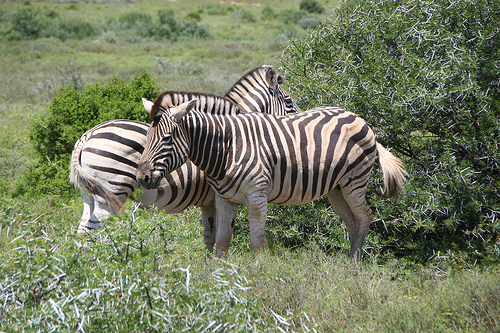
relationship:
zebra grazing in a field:
[134, 90, 412, 260] [1, 1, 483, 331]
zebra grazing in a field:
[66, 67, 303, 253] [1, 1, 483, 331]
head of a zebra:
[132, 91, 201, 191] [134, 90, 412, 260]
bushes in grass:
[6, 1, 212, 48] [1, 1, 241, 98]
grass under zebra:
[1, 196, 500, 333] [134, 98, 411, 261]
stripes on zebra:
[244, 113, 342, 201] [134, 90, 412, 260]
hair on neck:
[148, 90, 240, 119] [174, 103, 235, 183]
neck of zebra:
[174, 103, 235, 183] [134, 90, 412, 260]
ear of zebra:
[166, 95, 198, 123] [134, 90, 412, 260]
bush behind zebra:
[274, 0, 499, 264] [134, 98, 411, 261]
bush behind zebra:
[9, 70, 167, 203] [66, 67, 303, 253]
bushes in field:
[0, 0, 212, 40] [1, 1, 483, 331]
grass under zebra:
[1, 196, 476, 331] [134, 98, 411, 261]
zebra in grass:
[66, 64, 303, 252] [22, 26, 484, 320]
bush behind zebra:
[274, 0, 499, 264] [153, 65, 410, 272]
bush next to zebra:
[274, 0, 499, 264] [119, 60, 391, 242]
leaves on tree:
[362, 40, 444, 100] [271, 6, 472, 250]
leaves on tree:
[410, 180, 445, 222] [271, 6, 472, 250]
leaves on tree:
[410, 100, 443, 142] [271, 6, 472, 250]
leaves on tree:
[440, 51, 483, 126] [278, 7, 481, 257]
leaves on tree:
[384, 18, 464, 98] [278, 7, 481, 257]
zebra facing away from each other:
[134, 98, 411, 261] [59, 67, 411, 257]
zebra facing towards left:
[134, 90, 412, 260] [136, 85, 410, 260]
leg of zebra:
[244, 194, 271, 262] [134, 90, 412, 260]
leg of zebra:
[343, 170, 376, 262] [134, 90, 412, 260]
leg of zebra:
[206, 199, 236, 259] [134, 90, 412, 260]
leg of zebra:
[330, 190, 355, 247] [134, 90, 412, 260]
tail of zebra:
[376, 131, 413, 202] [134, 90, 412, 260]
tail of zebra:
[65, 128, 128, 208] [63, 59, 297, 241]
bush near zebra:
[268, 7, 480, 260] [134, 98, 411, 261]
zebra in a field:
[134, 98, 411, 261] [1, 1, 483, 331]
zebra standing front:
[134, 98, 411, 261] [136, 86, 191, 196]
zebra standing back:
[134, 98, 411, 261] [65, 115, 126, 244]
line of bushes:
[12, 7, 212, 42] [10, 4, 215, 39]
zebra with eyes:
[134, 90, 412, 260] [160, 130, 180, 143]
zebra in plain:
[134, 98, 411, 261] [2, 0, 484, 330]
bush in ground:
[9, 68, 166, 203] [1, 1, 229, 331]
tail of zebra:
[376, 140, 411, 199] [134, 90, 412, 260]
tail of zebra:
[68, 120, 126, 214] [66, 67, 303, 253]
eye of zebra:
[158, 132, 173, 143] [134, 90, 412, 260]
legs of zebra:
[210, 181, 377, 261] [134, 90, 412, 260]